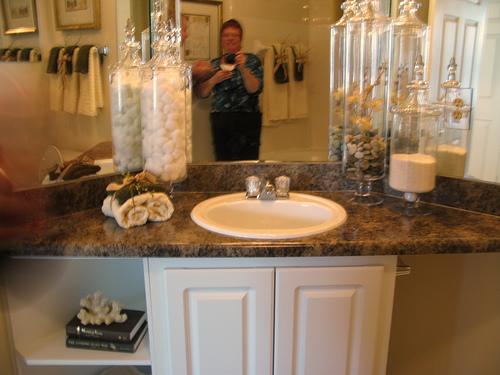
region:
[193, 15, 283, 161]
woman standing in the bathroom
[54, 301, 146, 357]
a stack of two books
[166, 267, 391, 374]
two white cabinet doors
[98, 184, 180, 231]
towels folded on the counter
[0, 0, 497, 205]
mirrors on the wall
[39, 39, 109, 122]
three towels hanging in a row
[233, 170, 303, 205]
two silver knobs on the sink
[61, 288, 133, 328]
figurine on top of the books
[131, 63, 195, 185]
a pile of cotton balls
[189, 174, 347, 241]
A white bathroom sink.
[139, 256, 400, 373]
Cupboards under a sink.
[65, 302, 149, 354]
Books on a shelf.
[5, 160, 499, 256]
A marble counter.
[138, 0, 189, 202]
Cotton balls in a jar.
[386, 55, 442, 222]
Soap in a jar.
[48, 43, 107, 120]
Towels on a rack.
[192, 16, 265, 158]
A lady in the mirror.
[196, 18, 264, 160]
A lady taking a selfie.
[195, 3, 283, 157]
woman is taking pictures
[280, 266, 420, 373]
drawer under the sink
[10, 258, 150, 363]
shelf under the counter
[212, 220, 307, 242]
lip of the sink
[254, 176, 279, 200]
faucest of the sink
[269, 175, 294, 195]
knob of the sink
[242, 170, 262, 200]
knob of the sink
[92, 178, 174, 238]
towel on the counter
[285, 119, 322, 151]
mirror on the counter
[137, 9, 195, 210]
Glass jar of cotton balls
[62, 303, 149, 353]
two black books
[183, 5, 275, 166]
reflection of woman in mirror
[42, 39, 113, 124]
towels hanging on a rack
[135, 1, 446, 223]
three tall glass jars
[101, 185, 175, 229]
rolled up white towel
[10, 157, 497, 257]
a brown countertop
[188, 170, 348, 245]
a white bathroom sink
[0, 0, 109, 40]
two pictures hanging on the wall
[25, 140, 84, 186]
toilet with the seat up